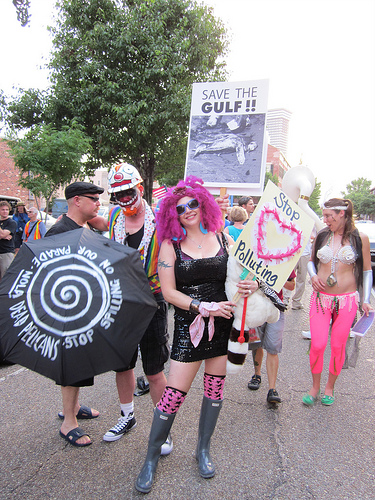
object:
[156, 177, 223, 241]
hair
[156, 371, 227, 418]
socks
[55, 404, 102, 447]
sandals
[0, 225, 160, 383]
umbrella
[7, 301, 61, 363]
dead pelicans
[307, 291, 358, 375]
pants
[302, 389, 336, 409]
shoes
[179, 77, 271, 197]
sign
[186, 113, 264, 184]
photo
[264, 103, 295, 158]
building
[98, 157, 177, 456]
man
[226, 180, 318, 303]
poster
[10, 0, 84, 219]
tree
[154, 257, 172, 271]
tattoo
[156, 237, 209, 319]
arm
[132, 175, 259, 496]
lady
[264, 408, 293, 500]
crack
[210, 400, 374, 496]
pavment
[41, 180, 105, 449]
man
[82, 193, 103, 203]
glasses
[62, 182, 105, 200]
cap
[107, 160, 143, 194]
hat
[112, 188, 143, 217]
face paint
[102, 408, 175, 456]
shoes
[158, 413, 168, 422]
label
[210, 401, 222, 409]
label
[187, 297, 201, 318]
bracelet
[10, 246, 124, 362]
writing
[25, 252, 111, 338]
design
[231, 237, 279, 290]
writing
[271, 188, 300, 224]
writing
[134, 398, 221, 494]
boots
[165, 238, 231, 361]
dress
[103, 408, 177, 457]
converse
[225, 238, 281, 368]
stuffed animal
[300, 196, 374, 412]
lady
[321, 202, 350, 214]
head band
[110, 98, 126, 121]
leaves